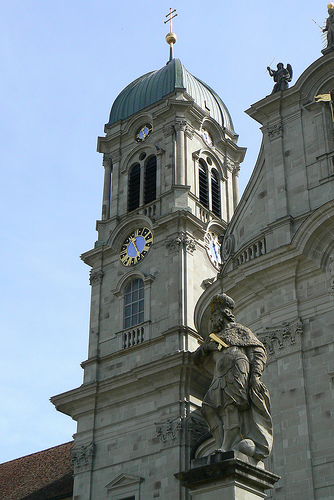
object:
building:
[0, 3, 334, 498]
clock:
[116, 228, 155, 268]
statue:
[265, 55, 295, 97]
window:
[197, 156, 224, 222]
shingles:
[105, 55, 247, 133]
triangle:
[129, 142, 156, 166]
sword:
[262, 41, 275, 77]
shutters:
[123, 162, 142, 214]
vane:
[162, 5, 187, 27]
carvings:
[192, 292, 275, 474]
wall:
[0, 436, 80, 500]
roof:
[102, 57, 240, 142]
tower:
[193, 0, 334, 500]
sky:
[0, 0, 327, 216]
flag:
[312, 89, 334, 125]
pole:
[158, 0, 183, 53]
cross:
[114, 273, 151, 339]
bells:
[117, 223, 153, 267]